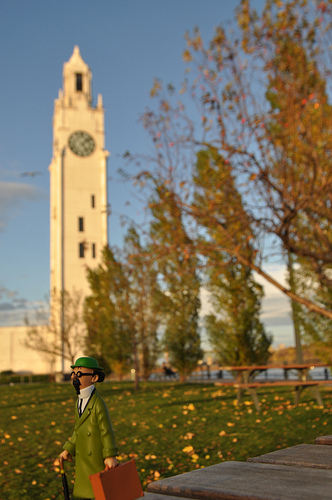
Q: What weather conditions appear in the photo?
A: It is clear.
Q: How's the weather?
A: It is clear.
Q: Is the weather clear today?
A: Yes, it is clear.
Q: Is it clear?
A: Yes, it is clear.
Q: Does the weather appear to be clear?
A: Yes, it is clear.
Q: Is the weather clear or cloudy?
A: It is clear.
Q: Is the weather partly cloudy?
A: No, it is clear.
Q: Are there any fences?
A: No, there are no fences.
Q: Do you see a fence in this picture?
A: No, there are no fences.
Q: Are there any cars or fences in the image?
A: No, there are no fences or cars.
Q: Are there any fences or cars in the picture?
A: No, there are no fences or cars.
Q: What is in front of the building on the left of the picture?
A: The tree is in front of the clock tower.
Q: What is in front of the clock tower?
A: The tree is in front of the clock tower.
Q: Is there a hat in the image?
A: Yes, there is a hat.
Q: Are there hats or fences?
A: Yes, there is a hat.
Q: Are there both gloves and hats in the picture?
A: No, there is a hat but no gloves.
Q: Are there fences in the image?
A: No, there are no fences.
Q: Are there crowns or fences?
A: No, there are no fences or crowns.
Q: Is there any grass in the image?
A: Yes, there is grass.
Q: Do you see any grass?
A: Yes, there is grass.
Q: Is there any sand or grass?
A: Yes, there is grass.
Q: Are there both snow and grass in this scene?
A: No, there is grass but no snow.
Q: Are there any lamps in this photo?
A: No, there are no lamps.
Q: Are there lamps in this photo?
A: No, there are no lamps.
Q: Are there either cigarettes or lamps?
A: No, there are no lamps or cigarettes.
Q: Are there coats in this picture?
A: Yes, there is a coat.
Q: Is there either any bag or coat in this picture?
A: Yes, there is a coat.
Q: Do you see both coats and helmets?
A: No, there is a coat but no helmets.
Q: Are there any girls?
A: No, there are no girls.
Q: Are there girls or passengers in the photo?
A: No, there are no girls or passengers.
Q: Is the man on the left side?
A: Yes, the man is on the left of the image.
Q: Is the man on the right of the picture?
A: No, the man is on the left of the image.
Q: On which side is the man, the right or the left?
A: The man is on the left of the image.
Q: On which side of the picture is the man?
A: The man is on the left of the image.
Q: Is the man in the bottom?
A: Yes, the man is in the bottom of the image.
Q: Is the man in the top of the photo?
A: No, the man is in the bottom of the image.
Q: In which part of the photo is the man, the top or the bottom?
A: The man is in the bottom of the image.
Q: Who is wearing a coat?
A: The man is wearing a coat.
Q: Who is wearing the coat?
A: The man is wearing a coat.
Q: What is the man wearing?
A: The man is wearing a coat.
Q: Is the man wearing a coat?
A: Yes, the man is wearing a coat.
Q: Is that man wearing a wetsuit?
A: No, the man is wearing a coat.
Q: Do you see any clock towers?
A: Yes, there is a clock tower.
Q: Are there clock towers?
A: Yes, there is a clock tower.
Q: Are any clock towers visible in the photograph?
A: Yes, there is a clock tower.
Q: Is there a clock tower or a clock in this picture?
A: Yes, there is a clock tower.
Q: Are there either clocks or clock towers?
A: Yes, there is a clock tower.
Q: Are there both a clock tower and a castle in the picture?
A: No, there is a clock tower but no castles.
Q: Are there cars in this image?
A: No, there are no cars.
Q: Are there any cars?
A: No, there are no cars.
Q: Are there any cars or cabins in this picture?
A: No, there are no cars or cabins.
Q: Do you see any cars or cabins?
A: No, there are no cars or cabins.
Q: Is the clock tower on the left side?
A: Yes, the clock tower is on the left of the image.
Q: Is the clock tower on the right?
A: No, the clock tower is on the left of the image.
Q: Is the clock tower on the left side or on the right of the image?
A: The clock tower is on the left of the image.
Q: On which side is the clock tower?
A: The clock tower is on the left of the image.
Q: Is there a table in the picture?
A: Yes, there is a table.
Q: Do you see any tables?
A: Yes, there is a table.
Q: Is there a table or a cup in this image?
A: Yes, there is a table.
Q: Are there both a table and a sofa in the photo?
A: No, there is a table but no sofas.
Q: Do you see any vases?
A: No, there are no vases.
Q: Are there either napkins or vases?
A: No, there are no vases or napkins.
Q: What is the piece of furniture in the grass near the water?
A: The piece of furniture is a table.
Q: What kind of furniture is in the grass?
A: The piece of furniture is a table.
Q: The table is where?
A: The table is in the grass.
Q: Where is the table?
A: The table is in the grass.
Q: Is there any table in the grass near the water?
A: Yes, there is a table in the grass.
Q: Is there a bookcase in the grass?
A: No, there is a table in the grass.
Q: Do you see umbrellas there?
A: Yes, there is an umbrella.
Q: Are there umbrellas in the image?
A: Yes, there is an umbrella.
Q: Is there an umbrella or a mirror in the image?
A: Yes, there is an umbrella.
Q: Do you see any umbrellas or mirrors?
A: Yes, there is an umbrella.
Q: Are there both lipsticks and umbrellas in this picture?
A: No, there is an umbrella but no lipsticks.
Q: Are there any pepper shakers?
A: No, there are no pepper shakers.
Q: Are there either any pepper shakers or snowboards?
A: No, there are no pepper shakers or snowboards.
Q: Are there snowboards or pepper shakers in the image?
A: No, there are no pepper shakers or snowboards.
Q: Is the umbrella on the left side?
A: Yes, the umbrella is on the left of the image.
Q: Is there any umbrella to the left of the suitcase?
A: Yes, there is an umbrella to the left of the suitcase.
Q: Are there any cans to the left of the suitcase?
A: No, there is an umbrella to the left of the suitcase.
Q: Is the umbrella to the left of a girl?
A: No, the umbrella is to the left of the suitcase.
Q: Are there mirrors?
A: No, there are no mirrors.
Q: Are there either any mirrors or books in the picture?
A: No, there are no mirrors or books.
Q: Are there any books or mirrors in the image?
A: No, there are no mirrors or books.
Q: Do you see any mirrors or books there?
A: No, there are no mirrors or books.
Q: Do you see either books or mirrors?
A: No, there are no mirrors or books.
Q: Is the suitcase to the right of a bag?
A: No, the suitcase is to the right of the umbrella.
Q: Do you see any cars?
A: No, there are no cars.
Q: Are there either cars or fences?
A: No, there are no cars or fences.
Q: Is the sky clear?
A: Yes, the sky is clear.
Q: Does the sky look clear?
A: Yes, the sky is clear.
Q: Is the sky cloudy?
A: No, the sky is clear.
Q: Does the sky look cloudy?
A: No, the sky is clear.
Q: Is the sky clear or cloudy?
A: The sky is clear.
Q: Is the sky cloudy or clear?
A: The sky is clear.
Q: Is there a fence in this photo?
A: No, there are no fences.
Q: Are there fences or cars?
A: No, there are no fences or cars.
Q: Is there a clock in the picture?
A: Yes, there is a clock.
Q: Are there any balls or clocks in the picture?
A: Yes, there is a clock.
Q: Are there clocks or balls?
A: Yes, there is a clock.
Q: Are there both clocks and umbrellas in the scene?
A: Yes, there are both a clock and an umbrella.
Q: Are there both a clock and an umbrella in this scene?
A: Yes, there are both a clock and an umbrella.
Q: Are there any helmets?
A: No, there are no helmets.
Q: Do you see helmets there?
A: No, there are no helmets.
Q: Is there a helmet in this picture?
A: No, there are no helmets.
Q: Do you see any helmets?
A: No, there are no helmets.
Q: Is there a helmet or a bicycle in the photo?
A: No, there are no helmets or bicycles.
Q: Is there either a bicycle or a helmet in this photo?
A: No, there are no helmets or bicycles.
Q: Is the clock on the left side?
A: Yes, the clock is on the left of the image.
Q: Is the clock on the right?
A: No, the clock is on the left of the image.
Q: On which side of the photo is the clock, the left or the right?
A: The clock is on the left of the image.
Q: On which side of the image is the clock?
A: The clock is on the left of the image.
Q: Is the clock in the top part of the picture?
A: Yes, the clock is in the top of the image.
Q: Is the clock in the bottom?
A: No, the clock is in the top of the image.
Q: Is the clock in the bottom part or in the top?
A: The clock is in the top of the image.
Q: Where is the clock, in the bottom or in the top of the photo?
A: The clock is in the top of the image.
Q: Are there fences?
A: No, there are no fences.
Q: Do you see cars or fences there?
A: No, there are no fences or cars.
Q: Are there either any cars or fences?
A: No, there are no fences or cars.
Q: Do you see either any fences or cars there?
A: No, there are no fences or cars.